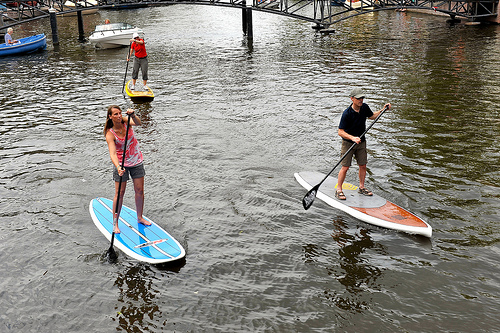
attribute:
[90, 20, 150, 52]
motor boat — white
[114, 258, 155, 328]
reflection — human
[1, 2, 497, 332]
water — dark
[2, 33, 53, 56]
boat — white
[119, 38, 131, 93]
paddle —  red shirt on yellow , for board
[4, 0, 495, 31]
bridge — long ,  metal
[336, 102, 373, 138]
t-shirt — black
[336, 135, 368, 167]
shorts — brown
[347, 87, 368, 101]
cap — gray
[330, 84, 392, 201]
man — up straight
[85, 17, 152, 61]
boat — white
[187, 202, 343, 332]
surface — dark, water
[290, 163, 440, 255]
paddle board — gray and orange , for paddle 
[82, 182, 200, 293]
paddleboard — white, blue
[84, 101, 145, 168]
tank top — orange, white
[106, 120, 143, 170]
shirt — pink ,  floral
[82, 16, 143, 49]
ship — white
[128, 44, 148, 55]
shirt — red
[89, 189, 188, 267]
boat — blue